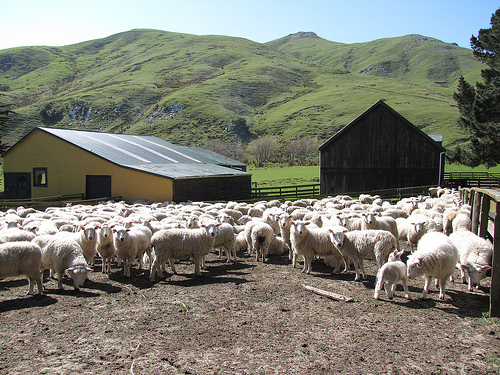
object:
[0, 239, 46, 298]
sheep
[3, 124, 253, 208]
building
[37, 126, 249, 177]
roof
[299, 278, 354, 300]
log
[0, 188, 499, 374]
ground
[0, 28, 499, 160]
hills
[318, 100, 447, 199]
house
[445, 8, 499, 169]
pine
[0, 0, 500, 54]
sky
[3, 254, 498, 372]
dirt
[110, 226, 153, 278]
sheep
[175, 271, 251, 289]
shadows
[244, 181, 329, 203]
fence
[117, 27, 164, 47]
grass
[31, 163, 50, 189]
window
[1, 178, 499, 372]
pen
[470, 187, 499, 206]
stick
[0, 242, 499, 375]
soil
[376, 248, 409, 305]
lamb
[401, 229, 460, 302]
sheep